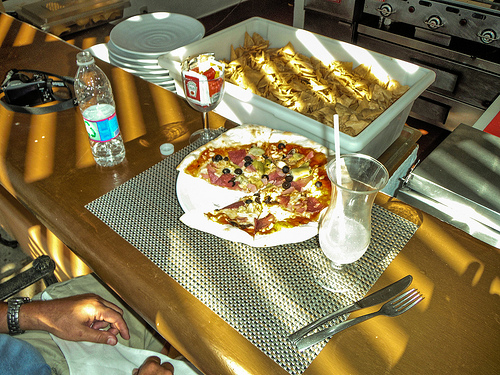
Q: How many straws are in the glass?
A: 1.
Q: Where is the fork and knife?
A: On the right.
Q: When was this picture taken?
A: Daytime.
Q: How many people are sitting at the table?
A: 1.